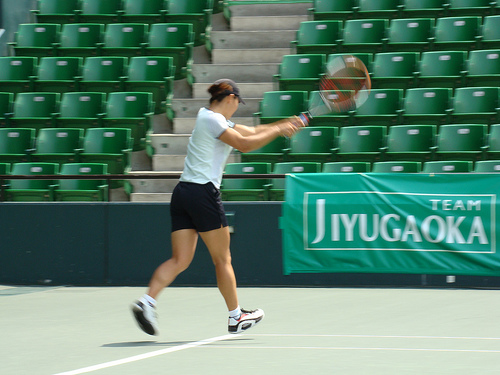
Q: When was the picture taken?
A: Daytime.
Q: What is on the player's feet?
A: Sneakers.